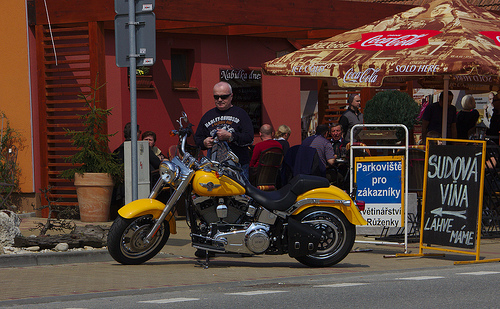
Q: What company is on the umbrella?
A: Coca Cola.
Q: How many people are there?
A: Ten.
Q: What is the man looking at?
A: The motorcycle.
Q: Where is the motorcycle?
A: On curb.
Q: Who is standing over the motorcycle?
A: A man.